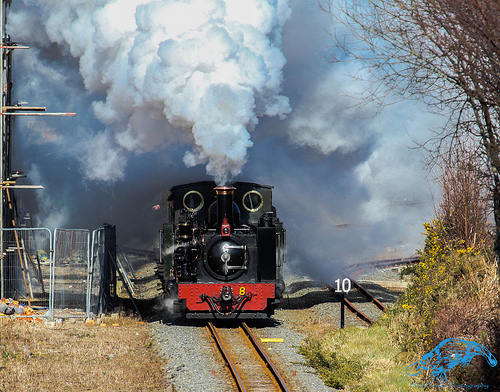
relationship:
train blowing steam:
[152, 179, 292, 326] [9, 5, 487, 272]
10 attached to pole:
[335, 276, 351, 294] [329, 272, 356, 327]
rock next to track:
[182, 338, 188, 343] [196, 322, 298, 389]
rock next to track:
[172, 361, 182, 372] [196, 322, 298, 389]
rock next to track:
[303, 376, 310, 382] [196, 322, 298, 389]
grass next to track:
[0, 299, 168, 390] [203, 321, 291, 390]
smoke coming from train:
[11, 0, 289, 178] [166, 172, 285, 319]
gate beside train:
[2, 219, 122, 321] [152, 179, 292, 326]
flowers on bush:
[379, 210, 498, 356] [392, 210, 497, 370]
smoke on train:
[11, 0, 289, 178] [148, 169, 300, 327]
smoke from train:
[11, 0, 289, 178] [134, 169, 301, 322]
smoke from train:
[11, 0, 289, 178] [152, 179, 292, 326]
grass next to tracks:
[0, 299, 168, 390] [206, 317, 292, 389]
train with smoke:
[152, 179, 287, 326] [48, 12, 310, 177]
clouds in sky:
[15, 13, 433, 253] [16, 3, 436, 277]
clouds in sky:
[15, 13, 433, 253] [10, 3, 493, 257]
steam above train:
[9, 5, 487, 272] [159, 160, 280, 322]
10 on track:
[335, 276, 351, 294] [167, 318, 332, 390]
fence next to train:
[5, 225, 117, 316] [21, 228, 112, 335]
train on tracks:
[152, 179, 292, 326] [206, 317, 292, 389]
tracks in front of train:
[206, 317, 292, 389] [177, 191, 270, 327]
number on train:
[237, 284, 247, 296] [166, 172, 285, 319]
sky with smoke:
[31, 10, 362, 185] [53, 8, 292, 180]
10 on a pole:
[335, 276, 354, 297] [337, 292, 350, 326]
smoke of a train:
[11, 0, 289, 178] [152, 179, 292, 326]